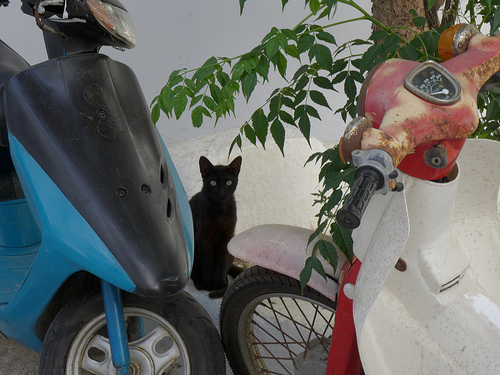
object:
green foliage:
[268, 116, 285, 158]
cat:
[188, 155, 245, 299]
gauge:
[402, 58, 462, 105]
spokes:
[246, 332, 291, 375]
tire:
[38, 288, 224, 375]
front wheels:
[37, 282, 227, 375]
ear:
[199, 156, 214, 178]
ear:
[226, 156, 242, 174]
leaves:
[249, 106, 270, 150]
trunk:
[370, 0, 432, 59]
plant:
[145, 0, 499, 297]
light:
[85, 0, 134, 49]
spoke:
[266, 295, 297, 369]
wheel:
[218, 265, 363, 375]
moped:
[0, 0, 229, 375]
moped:
[217, 23, 500, 374]